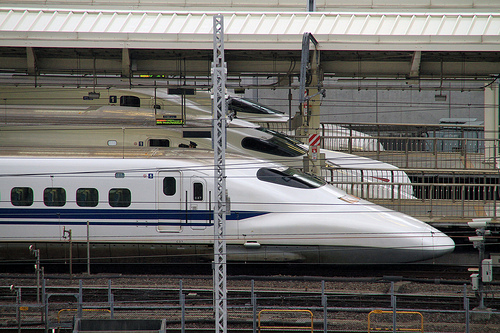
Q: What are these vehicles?
A: Trains.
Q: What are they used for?
A: Transportation.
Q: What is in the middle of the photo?
A: Pole.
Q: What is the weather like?
A: Overcast.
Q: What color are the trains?
A: White.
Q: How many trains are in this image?
A: Three.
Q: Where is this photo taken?
A: Train station.